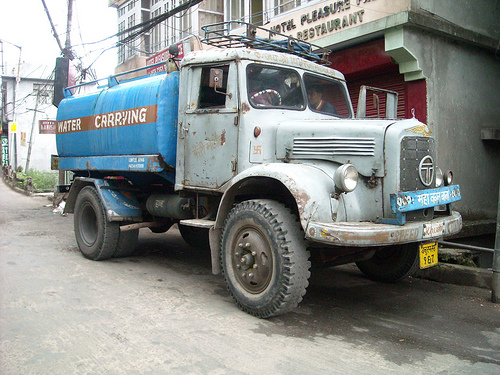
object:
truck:
[45, 19, 463, 318]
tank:
[51, 69, 185, 172]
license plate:
[414, 243, 447, 271]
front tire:
[214, 196, 314, 315]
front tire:
[355, 245, 420, 282]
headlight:
[331, 162, 361, 193]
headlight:
[433, 167, 443, 185]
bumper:
[301, 211, 467, 250]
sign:
[54, 103, 163, 138]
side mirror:
[206, 65, 224, 89]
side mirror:
[371, 92, 382, 119]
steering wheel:
[249, 88, 283, 108]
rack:
[201, 21, 335, 67]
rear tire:
[68, 183, 122, 262]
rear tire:
[176, 221, 210, 248]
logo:
[416, 155, 438, 188]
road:
[1, 173, 499, 375]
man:
[303, 86, 337, 117]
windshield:
[242, 60, 309, 112]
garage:
[323, 25, 457, 119]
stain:
[383, 310, 424, 342]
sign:
[388, 182, 463, 214]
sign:
[265, 0, 414, 44]